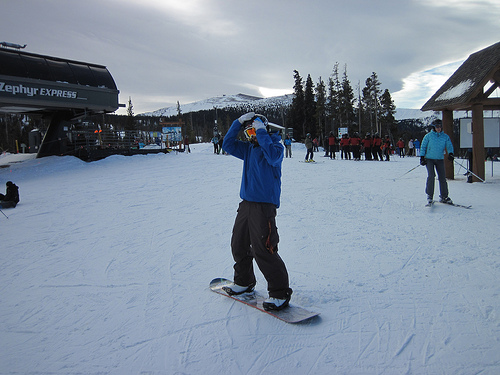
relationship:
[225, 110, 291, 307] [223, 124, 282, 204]
person wearing coat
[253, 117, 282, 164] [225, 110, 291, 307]
arm of person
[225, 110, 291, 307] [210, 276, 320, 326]
person on snowboard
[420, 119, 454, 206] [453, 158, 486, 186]
person holding ski pole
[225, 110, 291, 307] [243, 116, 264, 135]
person wearing helmet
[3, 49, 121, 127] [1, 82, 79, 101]
bus says zephyr express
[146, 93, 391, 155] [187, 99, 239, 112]
mountain covered in snow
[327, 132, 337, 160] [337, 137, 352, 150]
person wearing jacket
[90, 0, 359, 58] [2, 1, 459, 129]
cloud in sky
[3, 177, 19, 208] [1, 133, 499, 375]
person sitting on snow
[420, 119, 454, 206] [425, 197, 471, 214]
person standing on skies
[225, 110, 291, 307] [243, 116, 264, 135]
person holding helmet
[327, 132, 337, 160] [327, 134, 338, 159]
person in uniform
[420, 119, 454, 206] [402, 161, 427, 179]
person holding ski pole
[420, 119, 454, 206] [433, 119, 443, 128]
person wearing helmet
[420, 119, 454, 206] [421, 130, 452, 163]
person wearing coat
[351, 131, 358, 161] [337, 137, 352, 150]
person wearing jacket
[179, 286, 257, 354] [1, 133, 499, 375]
tracks in snow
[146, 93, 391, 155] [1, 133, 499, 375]
mountain covered in snow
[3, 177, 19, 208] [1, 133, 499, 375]
person covered on snow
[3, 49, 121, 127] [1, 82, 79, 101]
bus say zephyr express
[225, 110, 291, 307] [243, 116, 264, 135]
person fixing helmet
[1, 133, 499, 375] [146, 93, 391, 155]
snow on mountain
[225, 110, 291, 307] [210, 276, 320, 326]
person standing on snowboard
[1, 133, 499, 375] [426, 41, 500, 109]
snow on roof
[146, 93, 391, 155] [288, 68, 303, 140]
mountain behind pine tree